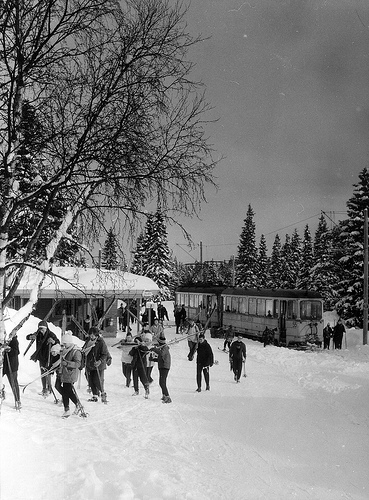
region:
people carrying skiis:
[24, 296, 262, 421]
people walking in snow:
[34, 309, 237, 411]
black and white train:
[167, 277, 331, 362]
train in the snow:
[171, 273, 340, 362]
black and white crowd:
[24, 317, 246, 413]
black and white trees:
[240, 199, 367, 304]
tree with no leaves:
[19, 35, 208, 210]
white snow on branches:
[0, 143, 94, 249]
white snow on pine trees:
[216, 203, 358, 302]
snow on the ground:
[173, 404, 360, 486]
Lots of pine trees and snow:
[108, 201, 364, 316]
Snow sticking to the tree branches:
[5, 190, 104, 349]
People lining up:
[13, 311, 250, 419]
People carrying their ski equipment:
[15, 290, 259, 423]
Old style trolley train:
[166, 268, 346, 367]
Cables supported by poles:
[176, 205, 349, 268]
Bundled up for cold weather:
[7, 307, 258, 426]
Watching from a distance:
[252, 290, 361, 364]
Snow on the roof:
[54, 252, 167, 300]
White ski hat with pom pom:
[58, 322, 81, 357]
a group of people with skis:
[0, 283, 251, 408]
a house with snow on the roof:
[0, 264, 160, 340]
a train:
[166, 281, 326, 353]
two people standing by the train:
[323, 317, 346, 353]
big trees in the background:
[184, 170, 365, 321]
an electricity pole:
[358, 211, 368, 341]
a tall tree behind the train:
[236, 201, 259, 290]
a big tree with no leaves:
[0, 9, 208, 341]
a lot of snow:
[14, 334, 364, 498]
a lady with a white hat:
[59, 328, 86, 418]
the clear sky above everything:
[177, 2, 358, 245]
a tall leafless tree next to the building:
[1, 0, 205, 296]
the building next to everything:
[15, 259, 158, 333]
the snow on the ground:
[6, 318, 361, 498]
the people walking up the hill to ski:
[10, 317, 259, 423]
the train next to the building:
[173, 282, 325, 348]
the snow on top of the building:
[3, 256, 156, 289]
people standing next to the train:
[321, 320, 344, 347]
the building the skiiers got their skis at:
[34, 300, 116, 335]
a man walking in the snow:
[193, 328, 211, 389]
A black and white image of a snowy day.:
[1, 3, 364, 494]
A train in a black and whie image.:
[162, 259, 341, 346]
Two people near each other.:
[184, 325, 257, 399]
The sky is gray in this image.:
[235, 78, 336, 185]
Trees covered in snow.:
[220, 188, 366, 279]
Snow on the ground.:
[142, 407, 357, 482]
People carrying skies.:
[7, 310, 185, 420]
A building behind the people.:
[2, 240, 167, 412]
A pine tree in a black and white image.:
[226, 184, 258, 282]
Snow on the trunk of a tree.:
[0, 171, 120, 337]